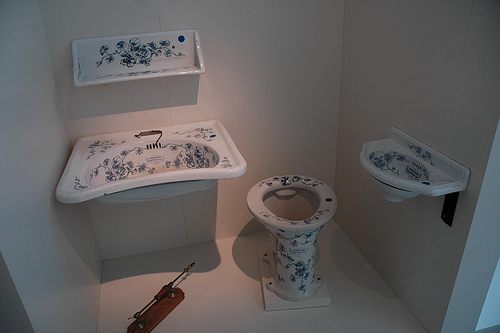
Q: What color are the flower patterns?
A: Blue.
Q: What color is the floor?
A: White.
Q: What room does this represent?
A: A bathroom.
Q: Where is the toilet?
A: Between the two basins.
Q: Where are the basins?
A: On the walls.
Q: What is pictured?
A: A decorative bathroom display.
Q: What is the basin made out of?
A: Porcelain.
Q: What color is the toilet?
A: Blue and white.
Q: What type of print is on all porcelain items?
A: Floral.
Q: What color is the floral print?
A: Blue.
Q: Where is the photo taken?
A: Bathroom.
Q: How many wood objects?
A: 1.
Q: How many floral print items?
A: 4.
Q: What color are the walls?
A: White.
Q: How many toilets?
A: 1.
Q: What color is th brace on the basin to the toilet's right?
A: Black.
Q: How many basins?
A: 2.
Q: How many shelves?
A: 1.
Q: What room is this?
A: Bathroom.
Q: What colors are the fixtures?
A: Blue and white.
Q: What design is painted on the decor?
A: Flowers.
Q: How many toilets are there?
A: One.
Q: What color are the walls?
A: White.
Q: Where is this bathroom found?
A: Dollhouse.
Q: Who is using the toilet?
A: No one.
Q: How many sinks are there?
A: Two.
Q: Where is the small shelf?
A: Wall.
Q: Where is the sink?
A: To the left.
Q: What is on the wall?
A: Shelf.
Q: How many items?
A: Five.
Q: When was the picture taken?
A: Nighttime.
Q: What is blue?
A: Flowers.